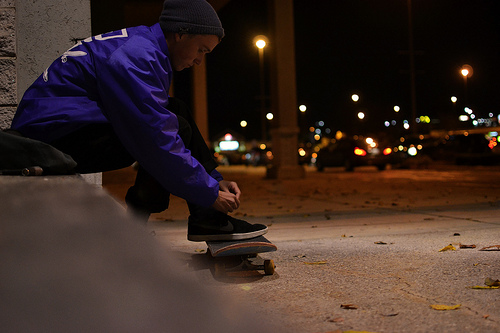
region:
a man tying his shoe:
[113, 23, 255, 327]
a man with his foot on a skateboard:
[171, 151, 296, 297]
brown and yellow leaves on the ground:
[329, 220, 495, 332]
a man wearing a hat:
[141, 9, 231, 69]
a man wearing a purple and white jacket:
[31, 12, 223, 149]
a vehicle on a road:
[309, 128, 397, 183]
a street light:
[439, 52, 491, 99]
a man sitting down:
[17, 19, 241, 189]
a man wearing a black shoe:
[151, 17, 243, 278]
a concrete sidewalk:
[329, 169, 464, 329]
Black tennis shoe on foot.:
[183, 200, 268, 241]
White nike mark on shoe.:
[186, 210, 267, 240]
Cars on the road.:
[304, 128, 499, 167]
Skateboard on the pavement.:
[185, 213, 292, 284]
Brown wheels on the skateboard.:
[205, 255, 285, 282]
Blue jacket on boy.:
[26, 10, 251, 233]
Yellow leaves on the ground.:
[425, 232, 497, 328]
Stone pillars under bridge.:
[266, 8, 311, 183]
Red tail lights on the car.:
[347, 145, 392, 160]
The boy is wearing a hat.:
[151, 0, 226, 95]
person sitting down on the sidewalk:
[9, 6, 284, 261]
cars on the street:
[297, 117, 499, 181]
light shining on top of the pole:
[248, 34, 275, 56]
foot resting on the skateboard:
[180, 203, 274, 252]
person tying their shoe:
[9, 6, 307, 281]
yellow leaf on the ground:
[432, 297, 461, 316]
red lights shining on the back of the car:
[347, 148, 397, 160]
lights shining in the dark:
[337, 89, 412, 125]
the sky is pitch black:
[93, 1, 498, 141]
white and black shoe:
[186, 203, 271, 241]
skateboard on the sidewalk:
[200, 220, 285, 282]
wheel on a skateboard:
[260, 257, 281, 277]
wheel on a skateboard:
[212, 258, 237, 282]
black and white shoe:
[177, 208, 274, 248]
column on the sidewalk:
[262, 3, 309, 180]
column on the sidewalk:
[185, 53, 215, 146]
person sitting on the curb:
[17, 2, 290, 278]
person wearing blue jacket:
[0, 0, 277, 300]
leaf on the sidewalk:
[435, 239, 480, 258]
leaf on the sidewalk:
[418, 298, 470, 316]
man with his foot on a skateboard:
[25, 0, 280, 281]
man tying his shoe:
[83, 3, 275, 248]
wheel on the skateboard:
[261, 257, 290, 290]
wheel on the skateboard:
[208, 249, 228, 280]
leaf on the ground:
[426, 289, 464, 326]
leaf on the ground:
[439, 238, 475, 265]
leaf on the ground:
[334, 287, 369, 318]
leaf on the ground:
[298, 247, 336, 277]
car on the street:
[428, 116, 496, 192]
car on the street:
[317, 123, 384, 187]